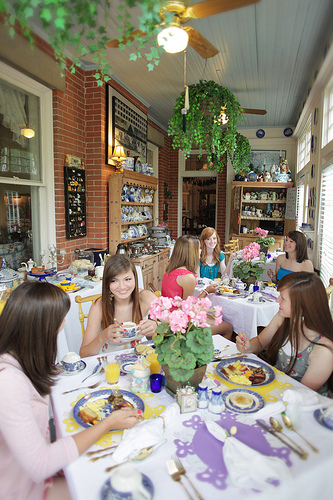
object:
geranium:
[166, 79, 248, 167]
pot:
[213, 97, 220, 117]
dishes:
[121, 184, 155, 202]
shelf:
[120, 200, 154, 208]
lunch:
[103, 317, 165, 376]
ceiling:
[2, 1, 332, 129]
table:
[49, 334, 333, 498]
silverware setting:
[167, 411, 319, 499]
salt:
[209, 389, 225, 414]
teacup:
[117, 322, 141, 338]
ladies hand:
[137, 316, 159, 338]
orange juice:
[104, 366, 121, 384]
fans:
[106, 0, 293, 128]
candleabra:
[41, 245, 67, 271]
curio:
[107, 168, 160, 253]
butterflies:
[174, 410, 292, 489]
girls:
[75, 235, 135, 368]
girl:
[235, 252, 331, 397]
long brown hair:
[267, 271, 332, 390]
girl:
[197, 226, 228, 281]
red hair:
[199, 226, 221, 267]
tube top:
[274, 265, 295, 284]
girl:
[267, 230, 314, 281]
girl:
[159, 231, 198, 312]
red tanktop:
[162, 268, 198, 302]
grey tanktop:
[270, 315, 325, 383]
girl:
[0, 280, 73, 496]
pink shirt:
[0, 351, 59, 494]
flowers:
[169, 308, 190, 338]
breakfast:
[51, 290, 330, 495]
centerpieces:
[149, 226, 275, 394]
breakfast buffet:
[230, 179, 298, 252]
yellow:
[206, 354, 295, 406]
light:
[214, 106, 231, 128]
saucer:
[115, 335, 140, 345]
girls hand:
[103, 322, 128, 344]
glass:
[101, 356, 121, 385]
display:
[121, 183, 155, 243]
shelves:
[120, 200, 153, 245]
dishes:
[121, 186, 155, 242]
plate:
[73, 389, 146, 429]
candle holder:
[149, 372, 163, 393]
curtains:
[2, 83, 32, 149]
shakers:
[207, 382, 227, 416]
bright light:
[157, 27, 188, 54]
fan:
[106, 1, 260, 58]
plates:
[253, 128, 292, 138]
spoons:
[279, 413, 319, 458]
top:
[196, 250, 225, 279]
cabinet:
[107, 170, 158, 254]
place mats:
[165, 402, 305, 496]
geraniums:
[147, 284, 225, 345]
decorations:
[218, 354, 273, 388]